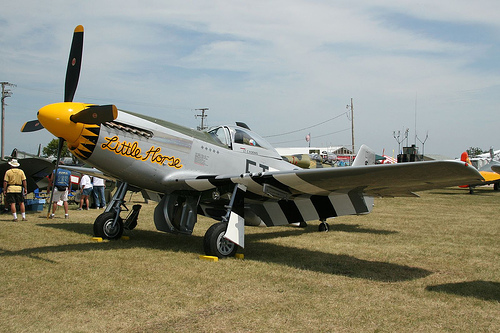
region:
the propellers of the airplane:
[17, 19, 118, 228]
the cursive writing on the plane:
[100, 130, 187, 174]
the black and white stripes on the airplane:
[198, 165, 365, 219]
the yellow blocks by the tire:
[89, 223, 106, 248]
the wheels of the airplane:
[94, 208, 239, 255]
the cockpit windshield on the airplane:
[209, 126, 276, 161]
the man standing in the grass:
[0, 156, 40, 224]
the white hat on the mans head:
[6, 155, 26, 168]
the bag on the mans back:
[53, 168, 74, 188]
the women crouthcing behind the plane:
[74, 170, 96, 217]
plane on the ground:
[23, 58, 475, 264]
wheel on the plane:
[206, 228, 236, 263]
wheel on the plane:
[90, 214, 135, 245]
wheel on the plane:
[158, 216, 198, 242]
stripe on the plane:
[277, 202, 296, 226]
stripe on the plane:
[316, 206, 331, 224]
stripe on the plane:
[352, 193, 374, 211]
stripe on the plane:
[247, 206, 282, 229]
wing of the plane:
[283, 163, 468, 203]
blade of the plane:
[73, 108, 133, 131]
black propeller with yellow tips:
[20, 19, 126, 178]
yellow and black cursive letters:
[101, 127, 188, 168]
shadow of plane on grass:
[3, 218, 432, 305]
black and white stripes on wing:
[190, 155, 372, 235]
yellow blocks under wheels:
[89, 210, 250, 263]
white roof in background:
[280, 143, 355, 161]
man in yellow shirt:
[0, 155, 32, 220]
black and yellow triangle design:
[76, 103, 104, 168]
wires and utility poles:
[1, 77, 358, 194]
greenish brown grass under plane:
[1, 179, 499, 331]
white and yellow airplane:
[20, 25, 497, 257]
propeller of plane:
[70, 104, 117, 124]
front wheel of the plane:
[93, 210, 125, 241]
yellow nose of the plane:
[35, 100, 84, 147]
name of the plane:
[101, 133, 183, 170]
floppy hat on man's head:
[8, 156, 21, 167]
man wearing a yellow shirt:
[3, 166, 25, 191]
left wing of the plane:
[168, 159, 485, 186]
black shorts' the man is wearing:
[6, 191, 26, 203]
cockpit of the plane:
[203, 122, 258, 146]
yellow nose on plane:
[42, 88, 93, 140]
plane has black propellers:
[5, 52, 117, 187]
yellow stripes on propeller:
[47, 21, 95, 49]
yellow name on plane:
[97, 118, 187, 194]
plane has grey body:
[120, 111, 298, 203]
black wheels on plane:
[38, 191, 275, 289]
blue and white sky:
[218, 13, 396, 175]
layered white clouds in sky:
[215, 25, 340, 127]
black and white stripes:
[247, 166, 370, 241]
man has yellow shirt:
[0, 157, 48, 214]